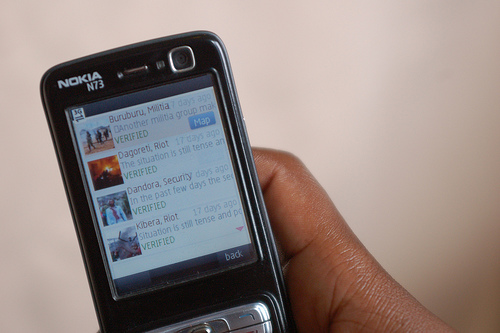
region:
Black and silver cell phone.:
[10, 6, 482, 321]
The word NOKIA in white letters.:
[50, 70, 106, 85]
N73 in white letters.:
[81, 77, 101, 97]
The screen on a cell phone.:
[61, 75, 264, 298]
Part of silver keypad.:
[147, 305, 278, 328]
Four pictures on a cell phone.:
[63, 93, 258, 305]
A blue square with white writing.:
[182, 106, 222, 136]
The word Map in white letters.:
[186, 107, 219, 134]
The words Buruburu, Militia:
[101, 98, 176, 125]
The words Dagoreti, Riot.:
[113, 136, 176, 164]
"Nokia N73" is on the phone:
[35, 34, 169, 105]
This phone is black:
[10, 30, 354, 331]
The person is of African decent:
[162, 83, 499, 325]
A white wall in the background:
[16, 16, 486, 216]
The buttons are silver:
[78, 290, 288, 330]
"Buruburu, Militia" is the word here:
[71, 86, 242, 146]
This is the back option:
[201, 227, 251, 268]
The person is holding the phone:
[10, 20, 430, 310]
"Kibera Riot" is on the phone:
[82, 192, 222, 249]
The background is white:
[49, 87, 273, 252]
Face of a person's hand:
[303, 131, 483, 331]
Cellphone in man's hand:
[25, 25, 465, 330]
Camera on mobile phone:
[165, 40, 195, 75]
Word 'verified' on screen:
[110, 126, 161, 141]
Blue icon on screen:
[182, 108, 218, 128]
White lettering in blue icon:
[187, 114, 214, 125]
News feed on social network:
[91, 95, 231, 257]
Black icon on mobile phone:
[211, 240, 258, 268]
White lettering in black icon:
[223, 248, 245, 260]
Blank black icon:
[112, 268, 162, 298]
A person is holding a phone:
[20, 40, 414, 330]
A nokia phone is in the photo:
[35, 4, 371, 326]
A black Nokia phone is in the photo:
[12, 22, 345, 328]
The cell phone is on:
[63, 28, 413, 331]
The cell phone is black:
[3, 44, 373, 324]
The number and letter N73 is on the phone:
[30, 24, 341, 329]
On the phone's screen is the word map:
[52, 44, 332, 325]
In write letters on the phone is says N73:
[30, 35, 325, 321]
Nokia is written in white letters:
[55, 30, 370, 314]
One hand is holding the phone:
[15, 45, 467, 331]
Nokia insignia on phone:
[51, 74, 104, 84]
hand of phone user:
[243, 137, 392, 330]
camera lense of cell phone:
[164, 50, 208, 75]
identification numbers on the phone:
[78, 76, 125, 104]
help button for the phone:
[179, 111, 232, 136]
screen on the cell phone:
[61, 104, 267, 276]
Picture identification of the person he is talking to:
[88, 152, 133, 194]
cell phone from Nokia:
[43, 63, 240, 326]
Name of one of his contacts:
[128, 168, 221, 203]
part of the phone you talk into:
[180, 320, 218, 332]